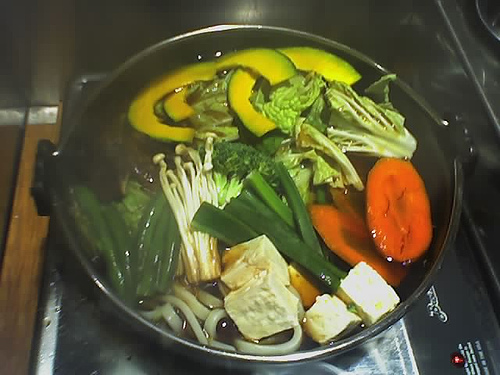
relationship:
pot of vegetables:
[32, 20, 474, 368] [76, 35, 438, 339]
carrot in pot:
[325, 179, 366, 220] [32, 20, 474, 368]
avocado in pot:
[225, 41, 361, 132] [32, 20, 474, 368]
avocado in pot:
[126, 38, 301, 150] [32, 20, 474, 368]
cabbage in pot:
[113, 163, 155, 221] [32, 20, 474, 368]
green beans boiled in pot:
[73, 174, 188, 308] [32, 20, 474, 368]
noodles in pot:
[147, 280, 307, 359] [32, 20, 474, 368]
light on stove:
[446, 351, 476, 372] [12, 282, 500, 374]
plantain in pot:
[284, 262, 322, 310] [32, 20, 474, 368]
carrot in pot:
[361, 155, 436, 265] [32, 20, 474, 368]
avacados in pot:
[225, 41, 361, 132] [32, 20, 474, 368]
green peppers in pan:
[104, 129, 155, 174] [32, 20, 474, 368]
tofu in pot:
[209, 235, 404, 350] [32, 20, 474, 368]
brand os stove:
[418, 277, 450, 329] [12, 282, 500, 374]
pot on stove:
[32, 20, 474, 368] [12, 282, 500, 374]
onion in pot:
[290, 167, 319, 202] [32, 20, 474, 368]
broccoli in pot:
[204, 134, 284, 205] [32, 20, 474, 368]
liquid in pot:
[67, 40, 441, 345] [32, 20, 474, 368]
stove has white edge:
[12, 282, 500, 374] [29, 226, 68, 370]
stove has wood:
[12, 282, 500, 374] [5, 112, 34, 372]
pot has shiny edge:
[32, 20, 474, 368] [209, 338, 380, 365]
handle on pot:
[22, 133, 57, 229] [32, 20, 474, 368]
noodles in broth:
[147, 280, 307, 359] [76, 35, 438, 339]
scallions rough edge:
[230, 163, 328, 263] [232, 161, 260, 193]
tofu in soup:
[209, 235, 404, 350] [76, 35, 438, 339]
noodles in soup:
[147, 280, 307, 359] [32, 20, 474, 368]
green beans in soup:
[73, 174, 188, 308] [76, 35, 438, 339]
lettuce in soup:
[287, 82, 418, 164] [76, 35, 438, 339]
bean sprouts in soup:
[150, 133, 225, 285] [76, 35, 438, 339]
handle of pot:
[22, 133, 57, 229] [32, 20, 474, 368]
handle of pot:
[440, 102, 481, 179] [32, 20, 474, 368]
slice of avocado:
[120, 44, 245, 165] [126, 38, 301, 150]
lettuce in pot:
[287, 82, 418, 164] [32, 20, 474, 368]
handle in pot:
[22, 133, 57, 229] [32, 20, 474, 368]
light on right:
[448, 351, 467, 368] [410, 315, 485, 373]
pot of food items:
[32, 20, 474, 368] [76, 35, 438, 339]